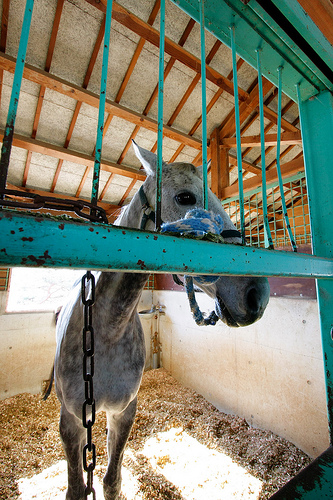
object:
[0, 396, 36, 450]
chips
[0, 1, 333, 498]
horse stall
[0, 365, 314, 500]
ground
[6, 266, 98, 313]
window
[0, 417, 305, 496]
sawdust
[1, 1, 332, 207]
ceiling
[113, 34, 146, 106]
rafter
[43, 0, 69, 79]
rafter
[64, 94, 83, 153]
rafter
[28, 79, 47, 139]
rafter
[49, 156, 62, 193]
rafter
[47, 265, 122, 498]
chain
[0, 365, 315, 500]
bedding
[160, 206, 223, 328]
rope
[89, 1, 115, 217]
bar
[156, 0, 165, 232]
bar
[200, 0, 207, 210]
bar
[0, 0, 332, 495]
aqua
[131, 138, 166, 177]
ear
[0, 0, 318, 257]
fence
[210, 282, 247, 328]
mouth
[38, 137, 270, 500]
horse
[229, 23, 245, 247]
bar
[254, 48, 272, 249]
bar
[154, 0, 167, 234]
metal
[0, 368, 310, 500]
floor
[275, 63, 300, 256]
bars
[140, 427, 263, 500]
light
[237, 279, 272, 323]
nose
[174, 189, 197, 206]
eye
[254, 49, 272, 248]
metal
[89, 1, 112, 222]
metal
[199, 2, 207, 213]
metal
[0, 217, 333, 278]
metal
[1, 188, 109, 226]
chain